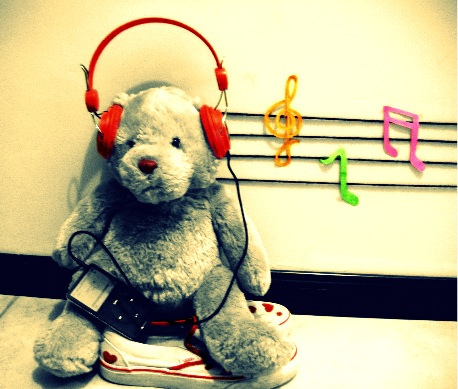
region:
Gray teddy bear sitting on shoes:
[30, 14, 304, 388]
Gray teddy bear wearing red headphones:
[30, 15, 301, 386]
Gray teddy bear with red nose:
[29, 14, 293, 383]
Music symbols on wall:
[225, 70, 455, 208]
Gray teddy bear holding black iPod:
[28, 13, 293, 383]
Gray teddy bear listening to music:
[31, 14, 295, 386]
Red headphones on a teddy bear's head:
[28, 14, 291, 387]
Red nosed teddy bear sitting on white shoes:
[28, 13, 296, 387]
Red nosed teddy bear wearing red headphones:
[29, 15, 301, 385]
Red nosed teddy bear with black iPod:
[29, 14, 302, 387]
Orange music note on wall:
[264, 60, 305, 164]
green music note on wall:
[317, 142, 362, 206]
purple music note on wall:
[381, 98, 424, 171]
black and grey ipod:
[62, 265, 153, 341]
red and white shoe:
[103, 320, 302, 387]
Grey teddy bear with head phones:
[33, 88, 284, 374]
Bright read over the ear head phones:
[82, 14, 231, 156]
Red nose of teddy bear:
[136, 156, 156, 174]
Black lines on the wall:
[225, 104, 455, 197]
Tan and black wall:
[1, 12, 453, 319]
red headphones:
[67, 18, 244, 161]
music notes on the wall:
[258, 71, 437, 198]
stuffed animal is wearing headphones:
[81, 18, 238, 178]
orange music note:
[260, 56, 306, 165]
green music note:
[322, 144, 369, 215]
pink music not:
[368, 100, 429, 173]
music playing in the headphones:
[42, 240, 172, 346]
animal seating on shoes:
[57, 227, 318, 385]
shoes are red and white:
[96, 330, 340, 387]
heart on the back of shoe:
[93, 347, 120, 373]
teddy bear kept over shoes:
[40, 279, 304, 386]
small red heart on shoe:
[262, 300, 275, 311]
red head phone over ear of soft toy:
[82, 17, 233, 157]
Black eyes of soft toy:
[169, 136, 181, 148]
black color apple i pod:
[68, 265, 153, 335]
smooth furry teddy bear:
[120, 208, 202, 260]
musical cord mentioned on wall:
[262, 71, 304, 167]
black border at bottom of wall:
[305, 271, 454, 321]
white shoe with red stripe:
[99, 331, 206, 386]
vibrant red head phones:
[74, 10, 234, 162]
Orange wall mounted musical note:
[263, 66, 308, 158]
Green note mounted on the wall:
[319, 139, 367, 196]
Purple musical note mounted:
[380, 93, 425, 172]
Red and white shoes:
[104, 326, 225, 387]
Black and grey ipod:
[60, 227, 168, 335]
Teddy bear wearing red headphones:
[32, 88, 298, 387]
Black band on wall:
[1, 250, 456, 324]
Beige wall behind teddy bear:
[1, 0, 453, 291]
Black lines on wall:
[223, 108, 455, 194]